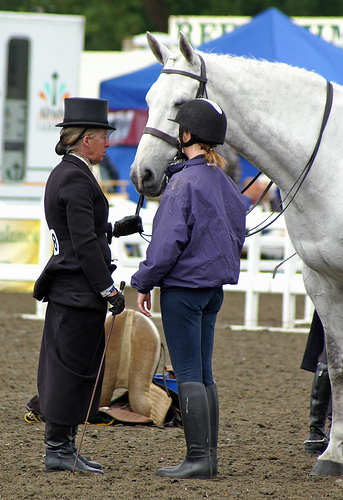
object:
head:
[53, 98, 111, 164]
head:
[173, 96, 225, 158]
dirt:
[0, 282, 342, 499]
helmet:
[166, 98, 228, 149]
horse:
[129, 27, 343, 477]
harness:
[240, 81, 333, 240]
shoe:
[307, 457, 342, 478]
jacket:
[129, 159, 248, 297]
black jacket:
[31, 153, 119, 305]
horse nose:
[128, 165, 158, 190]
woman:
[41, 97, 125, 475]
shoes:
[303, 360, 330, 454]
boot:
[68, 422, 103, 471]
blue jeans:
[159, 282, 224, 386]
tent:
[98, 8, 342, 252]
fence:
[0, 184, 317, 334]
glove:
[108, 289, 126, 317]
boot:
[155, 379, 212, 480]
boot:
[203, 380, 219, 479]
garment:
[30, 152, 118, 426]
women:
[129, 98, 247, 480]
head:
[129, 29, 203, 198]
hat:
[55, 97, 117, 132]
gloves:
[113, 212, 144, 240]